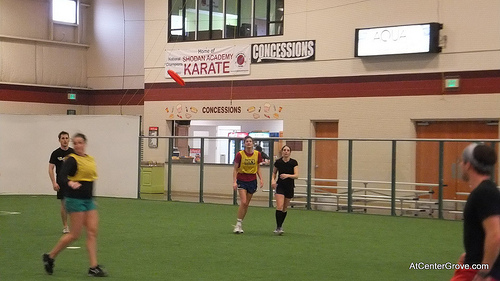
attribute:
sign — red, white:
[173, 56, 241, 74]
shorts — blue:
[56, 193, 100, 215]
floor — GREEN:
[1, 193, 466, 279]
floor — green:
[5, 191, 499, 278]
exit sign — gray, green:
[65, 89, 77, 101]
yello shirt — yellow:
[211, 153, 312, 188]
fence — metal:
[138, 133, 498, 218]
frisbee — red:
[166, 68, 186, 88]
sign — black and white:
[246, 37, 318, 65]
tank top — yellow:
[240, 153, 258, 173]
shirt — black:
[439, 171, 495, 274]